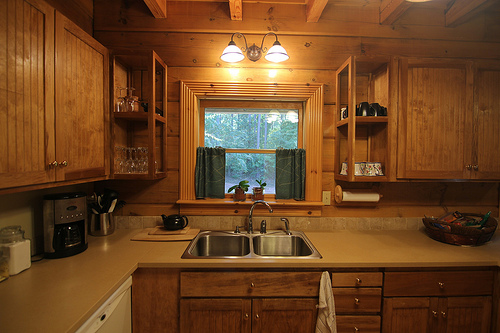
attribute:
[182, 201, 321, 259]
sink — silver, polished, stainless, still, stainless steel, above drawer, above cupboards, left of 3 drawers, two-sided, steel, a tap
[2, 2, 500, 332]
kitchen — pictured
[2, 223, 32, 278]
jar — glass, clear, filled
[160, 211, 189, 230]
teapot — black, a kettle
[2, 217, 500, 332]
counter — brown, light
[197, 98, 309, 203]
window — small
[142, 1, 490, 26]
beams — wooden, the ceiling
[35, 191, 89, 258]
coffee maker — silver, black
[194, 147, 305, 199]
curtains — green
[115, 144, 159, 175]
glasses — on shelf, clear, on shelves, on open shelves, for wine, cups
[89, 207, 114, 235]
container — holding utensils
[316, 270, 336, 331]
towel — hanging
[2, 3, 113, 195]
cabinets — on left, wood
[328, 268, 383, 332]
row of drawers — wooden, small